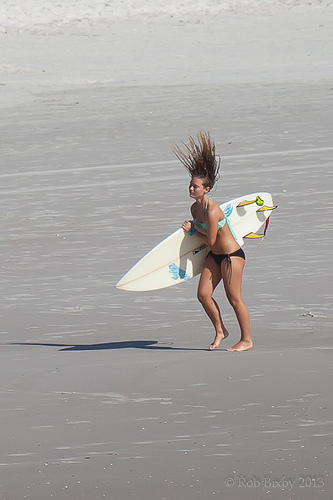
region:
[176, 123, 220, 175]
the hair of a woman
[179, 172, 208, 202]
the head of a woman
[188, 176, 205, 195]
the face of a woman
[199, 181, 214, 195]
the ear of a woman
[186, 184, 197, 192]
the nose of a woman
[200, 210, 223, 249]
the arm of a woman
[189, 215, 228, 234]
the bikini top of a woman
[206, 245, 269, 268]
the bikini bottoms of a woman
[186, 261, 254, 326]
the legs of a woman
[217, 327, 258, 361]
the foot of a woman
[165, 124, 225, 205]
girl flipping her brown hair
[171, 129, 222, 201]
girl flipping her hair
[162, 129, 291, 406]
girl on wet sand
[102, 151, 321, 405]
girl holding big white surboard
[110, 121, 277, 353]
girl with blue top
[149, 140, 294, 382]
girl with black bottoms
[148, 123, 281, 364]
girl holding blue and white surfboard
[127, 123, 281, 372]
girl with bathing suit on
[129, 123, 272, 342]
girl brown hair standing up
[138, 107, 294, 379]
girl walking on the beach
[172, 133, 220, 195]
woman with her hair blowing up in the wind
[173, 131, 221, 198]
woman with long brown hair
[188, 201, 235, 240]
woman wearing a green bikini top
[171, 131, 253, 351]
woman walking on wet sand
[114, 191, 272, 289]
a white surfboard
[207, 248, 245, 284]
woman wearing a black bikini bottom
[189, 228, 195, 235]
woman wearing a blue wristband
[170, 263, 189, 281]
a blue graffiti on a surfboard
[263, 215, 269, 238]
a red strap on a sufboard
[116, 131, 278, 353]
a woman carrying a surfboard on the beach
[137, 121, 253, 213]
a woman with long brown hair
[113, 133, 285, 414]
a woman standing on the beach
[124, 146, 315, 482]
a woman standing on sand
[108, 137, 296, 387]
a woman holding a surfboard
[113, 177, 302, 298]
a white surfboard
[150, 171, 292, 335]
a woman wearing a swim suit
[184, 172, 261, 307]
a woman wearing a bikini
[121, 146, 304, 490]
a woman holding a surfboard on the sand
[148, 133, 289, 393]
a woman holding a surfboard on the beach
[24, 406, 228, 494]
sand on the beach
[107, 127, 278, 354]
WOMAN WALKING WITH SURFBOARD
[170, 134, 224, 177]
WINDBLOWN HAIR OF WALKING WOMAN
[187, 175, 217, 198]
HEAD OF WALKING WOMAN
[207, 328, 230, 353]
FOOT OF WALKING WOMAN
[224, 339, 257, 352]
FOOT OF WALKING WOMAN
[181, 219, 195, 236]
HAND OF WALKING WOMAN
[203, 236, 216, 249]
ELBOW OF WALKING WOMAN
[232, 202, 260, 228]
PART OF WOMAN'S SURFBOARD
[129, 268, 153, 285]
PART OF WOMAN'S SURFBOARD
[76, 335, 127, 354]
DARK SHADOW OF WOMAN